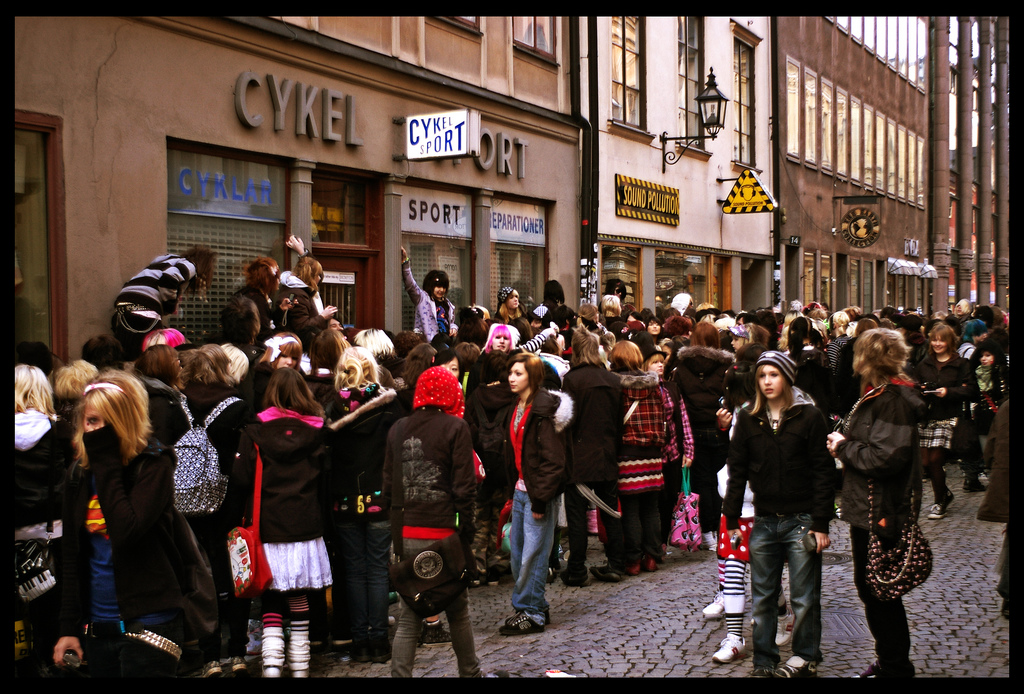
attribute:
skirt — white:
[256, 532, 340, 597]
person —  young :
[717, 337, 841, 679]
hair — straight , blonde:
[63, 365, 163, 477]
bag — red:
[181, 418, 307, 645]